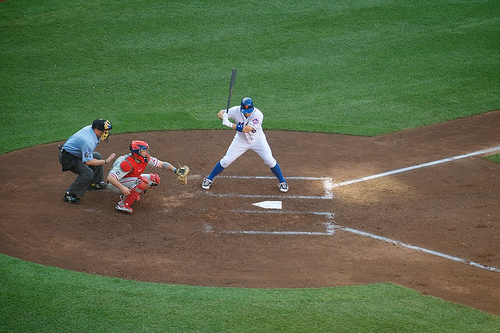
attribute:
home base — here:
[251, 191, 293, 217]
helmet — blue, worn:
[236, 95, 264, 116]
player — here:
[205, 108, 299, 197]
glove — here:
[168, 162, 206, 190]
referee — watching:
[57, 112, 111, 201]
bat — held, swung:
[224, 67, 242, 117]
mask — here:
[133, 134, 157, 163]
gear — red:
[125, 156, 159, 193]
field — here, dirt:
[173, 12, 488, 144]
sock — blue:
[266, 156, 293, 191]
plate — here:
[236, 196, 291, 221]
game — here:
[33, 17, 439, 296]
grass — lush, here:
[322, 1, 442, 112]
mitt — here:
[174, 165, 202, 182]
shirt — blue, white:
[58, 124, 105, 159]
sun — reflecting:
[320, 145, 395, 208]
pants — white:
[227, 137, 288, 168]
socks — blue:
[203, 162, 228, 179]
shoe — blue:
[275, 180, 295, 201]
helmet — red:
[133, 134, 147, 153]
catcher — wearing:
[104, 131, 193, 223]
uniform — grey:
[103, 154, 129, 200]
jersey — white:
[227, 112, 278, 169]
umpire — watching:
[69, 126, 99, 199]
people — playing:
[49, 76, 333, 259]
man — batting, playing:
[199, 86, 305, 193]